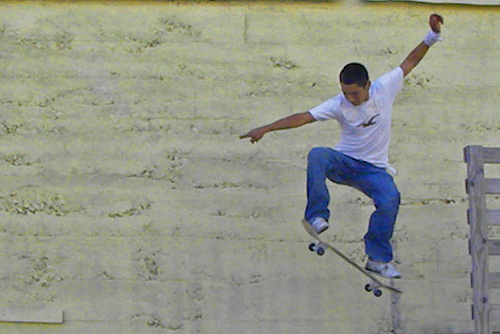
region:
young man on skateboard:
[235, 10, 446, 296]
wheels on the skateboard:
[366, 279, 384, 296]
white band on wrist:
[423, 28, 436, 43]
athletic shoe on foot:
[369, 258, 396, 277]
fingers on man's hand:
[240, 129, 259, 144]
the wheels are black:
[307, 240, 324, 257]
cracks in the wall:
[90, 147, 213, 326]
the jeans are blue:
[306, 143, 400, 245]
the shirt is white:
[335, 92, 400, 177]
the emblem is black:
[357, 112, 380, 131]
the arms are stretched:
[244, 85, 344, 148]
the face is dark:
[342, 78, 359, 105]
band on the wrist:
[420, 27, 441, 52]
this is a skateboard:
[283, 218, 409, 298]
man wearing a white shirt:
[286, 56, 414, 168]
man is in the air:
[203, 8, 478, 331]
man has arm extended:
[203, 63, 325, 157]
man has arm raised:
[368, 3, 460, 93]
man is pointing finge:
[239, 126, 254, 147]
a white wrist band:
[416, 23, 444, 48]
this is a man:
[230, 9, 472, 306]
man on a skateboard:
[223, 12, 488, 324]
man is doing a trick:
[220, 0, 490, 311]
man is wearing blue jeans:
[286, 135, 428, 260]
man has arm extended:
[219, 57, 339, 183]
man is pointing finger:
[234, 125, 250, 145]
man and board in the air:
[173, 0, 493, 315]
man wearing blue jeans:
[296, 147, 409, 249]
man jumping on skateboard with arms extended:
[241, 9, 452, 294]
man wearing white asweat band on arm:
[421, 28, 438, 50]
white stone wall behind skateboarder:
[12, 15, 495, 329]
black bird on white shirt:
[353, 105, 384, 135]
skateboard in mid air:
[293, 212, 419, 302]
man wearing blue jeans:
[291, 143, 401, 263]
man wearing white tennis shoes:
[312, 209, 427, 284]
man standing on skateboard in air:
[238, 8, 445, 303]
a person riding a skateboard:
[228, 8, 459, 317]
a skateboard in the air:
[283, 205, 413, 311]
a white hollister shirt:
[297, 47, 406, 178]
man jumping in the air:
[226, 11, 471, 311]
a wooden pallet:
[457, 120, 497, 328]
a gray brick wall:
[10, 13, 278, 307]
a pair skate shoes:
[293, 209, 423, 287]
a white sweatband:
[412, 19, 457, 49]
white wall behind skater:
[0, 17, 273, 317]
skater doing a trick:
[218, 4, 446, 289]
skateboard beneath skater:
[299, 212, 409, 310]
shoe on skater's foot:
[313, 207, 335, 234]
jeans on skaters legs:
[296, 136, 404, 254]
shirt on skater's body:
[307, 68, 409, 177]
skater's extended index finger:
[236, 127, 248, 149]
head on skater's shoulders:
[336, 50, 371, 103]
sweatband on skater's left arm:
[418, 26, 443, 51]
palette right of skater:
[453, 137, 499, 307]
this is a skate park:
[10, 28, 437, 330]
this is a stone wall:
[58, 75, 241, 279]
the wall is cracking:
[14, 49, 209, 254]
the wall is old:
[92, 95, 212, 282]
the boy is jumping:
[205, 50, 479, 292]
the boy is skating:
[241, 94, 444, 316]